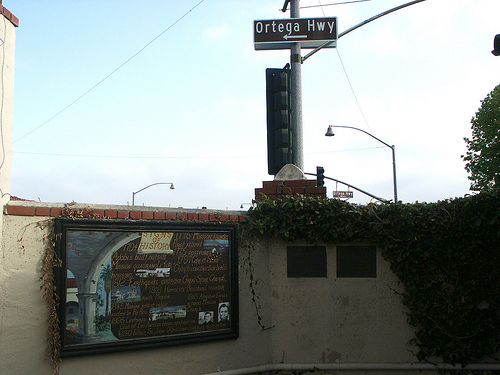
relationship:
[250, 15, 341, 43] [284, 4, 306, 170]
directional sign attached to utility pole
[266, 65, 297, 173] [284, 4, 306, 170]
traffic light attached to utility pole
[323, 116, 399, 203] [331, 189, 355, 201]
streetlight used for street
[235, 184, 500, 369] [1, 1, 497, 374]
ivy growing on wall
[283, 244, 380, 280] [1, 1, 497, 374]
plaques are attached to wall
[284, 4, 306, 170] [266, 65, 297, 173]
utility pole supporting traffic light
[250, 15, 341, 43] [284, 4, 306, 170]
street sign attached to utility pole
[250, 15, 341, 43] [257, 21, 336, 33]
directional sign reads ortega hwy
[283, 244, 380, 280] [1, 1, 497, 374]
plaques are on wall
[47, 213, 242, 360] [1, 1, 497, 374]
sign on top of building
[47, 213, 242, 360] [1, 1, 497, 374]
picture on side of building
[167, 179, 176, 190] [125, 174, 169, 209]
streetlight on pole